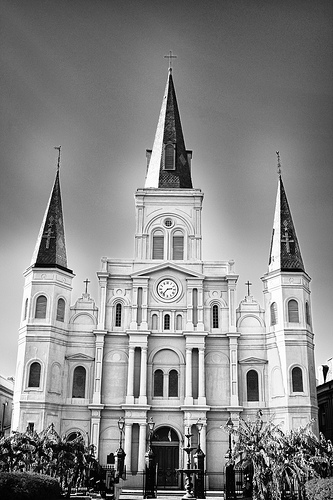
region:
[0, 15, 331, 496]
church in the forefront.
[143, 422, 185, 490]
door in the church.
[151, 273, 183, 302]
clock on the church.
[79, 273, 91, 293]
Cross on the building.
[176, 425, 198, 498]
Fountain in front of the church.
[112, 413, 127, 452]
Light post in front of the church.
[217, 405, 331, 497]
Trees in the forefront.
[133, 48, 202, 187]
Steeple on the church.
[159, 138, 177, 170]
Window on the church.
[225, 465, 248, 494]
Black wrought iron fence.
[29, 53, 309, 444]
a tall white church building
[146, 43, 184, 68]
a cross on a church building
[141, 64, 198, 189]
a roof on a church building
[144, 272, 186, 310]
a clock on a church building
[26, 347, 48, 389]
a window on a church building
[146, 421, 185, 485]
a door on a church building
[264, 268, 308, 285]
the ridges of a roof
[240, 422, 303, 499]
a small tree in front of a church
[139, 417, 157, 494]
a big tall lamp post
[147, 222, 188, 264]
a window with some shutters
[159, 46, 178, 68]
the cross on the top of the spire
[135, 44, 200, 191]
the tower with the cross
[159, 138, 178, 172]
the window on the tower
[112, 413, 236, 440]
the lights in front of the building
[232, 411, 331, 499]
the trees in front of the fence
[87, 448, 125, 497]
the fence in front of the church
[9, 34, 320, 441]
The church in front of the fence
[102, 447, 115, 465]
the sign on the wall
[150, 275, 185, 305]
the face fo the clock on the front of the building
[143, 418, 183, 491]
the front door of the church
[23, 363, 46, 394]
this is a window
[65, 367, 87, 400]
this is a window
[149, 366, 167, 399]
this is a window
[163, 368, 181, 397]
this is a window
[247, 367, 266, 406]
this is a window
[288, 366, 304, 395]
this is a window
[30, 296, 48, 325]
this is a window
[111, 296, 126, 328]
this is a window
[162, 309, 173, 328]
this is a window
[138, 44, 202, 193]
top of the building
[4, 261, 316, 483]
the building is tall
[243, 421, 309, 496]
plants inf ront of building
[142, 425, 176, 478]
door of the building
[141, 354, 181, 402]
window of the building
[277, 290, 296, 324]
windows of the building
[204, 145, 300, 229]
the sky is hazy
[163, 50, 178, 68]
The highest cross.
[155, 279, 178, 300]
Round white and black clock.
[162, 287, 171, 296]
Black hands on a clock.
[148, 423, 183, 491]
Largest arched doorway.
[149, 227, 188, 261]
Two arches over a clock.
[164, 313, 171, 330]
Middle black arch under a clock.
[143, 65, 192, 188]
Highest steeple on a church.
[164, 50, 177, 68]
The highest cross on a steeple.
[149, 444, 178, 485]
Large double brown door.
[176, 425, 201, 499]
A statue with three round shelves all different sizes.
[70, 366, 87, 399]
glass window on the building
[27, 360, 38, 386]
glass window on the building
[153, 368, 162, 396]
glass window on the building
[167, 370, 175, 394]
glass window on the building